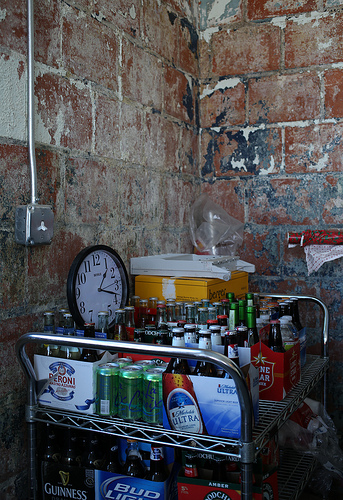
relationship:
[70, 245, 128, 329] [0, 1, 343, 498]
clock in front of wall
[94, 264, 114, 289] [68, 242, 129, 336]
hand on clock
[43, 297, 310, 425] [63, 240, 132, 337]
beers in front of clock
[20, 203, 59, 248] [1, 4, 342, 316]
light switch on wall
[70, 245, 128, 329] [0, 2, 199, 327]
clock near wall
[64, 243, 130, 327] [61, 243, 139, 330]
black frame around a clock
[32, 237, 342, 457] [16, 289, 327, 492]
beer lying on a metal cart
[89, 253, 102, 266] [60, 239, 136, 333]
number on a clock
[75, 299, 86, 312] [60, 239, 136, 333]
number on a clock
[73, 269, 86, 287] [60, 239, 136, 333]
number on a clock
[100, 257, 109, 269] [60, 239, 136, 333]
number on a clock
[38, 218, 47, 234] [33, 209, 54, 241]
switch on light